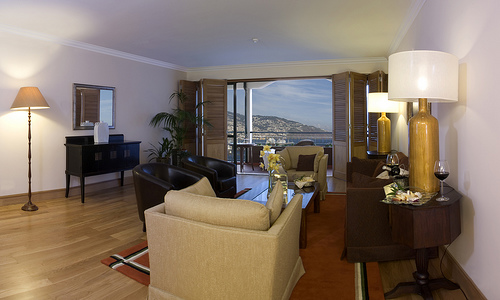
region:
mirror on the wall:
[64, 79, 124, 131]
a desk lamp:
[385, 43, 465, 200]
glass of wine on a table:
[430, 154, 456, 209]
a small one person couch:
[131, 169, 311, 299]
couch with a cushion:
[268, 136, 337, 205]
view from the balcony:
[219, 69, 343, 178]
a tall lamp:
[9, 72, 78, 229]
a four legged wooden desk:
[58, 127, 147, 200]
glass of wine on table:
[376, 144, 403, 193]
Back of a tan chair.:
[142, 176, 302, 297]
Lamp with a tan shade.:
[7, 85, 47, 212]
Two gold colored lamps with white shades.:
[367, 52, 458, 193]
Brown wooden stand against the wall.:
[65, 135, 140, 203]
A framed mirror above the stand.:
[71, 80, 117, 131]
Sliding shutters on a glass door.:
[328, 72, 368, 179]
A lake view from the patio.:
[228, 80, 331, 171]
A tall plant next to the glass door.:
[145, 77, 211, 165]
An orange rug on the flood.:
[96, 187, 382, 298]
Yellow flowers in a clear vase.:
[255, 136, 291, 201]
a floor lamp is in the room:
[3, 73, 59, 219]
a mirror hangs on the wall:
[70, 78, 129, 132]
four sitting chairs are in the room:
[114, 133, 345, 294]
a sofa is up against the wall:
[336, 146, 428, 253]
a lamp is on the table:
[383, 41, 460, 204]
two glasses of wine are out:
[378, 148, 453, 200]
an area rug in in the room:
[93, 180, 383, 297]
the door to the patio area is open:
[234, 85, 345, 178]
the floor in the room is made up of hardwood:
[29, 175, 126, 297]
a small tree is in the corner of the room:
[140, 69, 210, 178]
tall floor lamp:
[12, 85, 47, 215]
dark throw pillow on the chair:
[296, 153, 314, 175]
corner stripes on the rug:
[104, 246, 149, 275]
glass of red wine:
[434, 159, 449, 200]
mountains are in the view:
[226, 110, 325, 141]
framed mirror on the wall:
[70, 83, 117, 129]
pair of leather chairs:
[135, 152, 235, 227]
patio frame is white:
[228, 81, 269, 143]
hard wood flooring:
[2, 178, 152, 296]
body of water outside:
[227, 138, 335, 157]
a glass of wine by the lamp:
[424, 151, 453, 206]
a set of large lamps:
[358, 44, 471, 201]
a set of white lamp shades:
[358, 47, 470, 115]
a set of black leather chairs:
[127, 146, 242, 236]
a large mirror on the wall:
[63, 77, 126, 134]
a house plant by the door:
[146, 83, 219, 169]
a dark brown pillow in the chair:
[293, 150, 317, 175]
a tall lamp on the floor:
[2, 81, 53, 226]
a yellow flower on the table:
[251, 143, 284, 205]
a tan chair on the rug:
[131, 175, 310, 299]